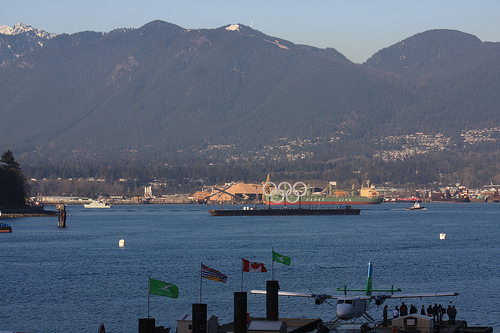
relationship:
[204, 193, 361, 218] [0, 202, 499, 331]
boat in water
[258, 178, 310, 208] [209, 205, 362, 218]
olympic rings on boat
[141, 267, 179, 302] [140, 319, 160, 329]
flag on post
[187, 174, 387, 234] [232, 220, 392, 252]
boat in water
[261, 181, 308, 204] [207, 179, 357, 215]
logo on boat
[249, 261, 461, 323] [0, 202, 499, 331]
airplane on water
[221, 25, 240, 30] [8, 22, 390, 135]
snow on mountain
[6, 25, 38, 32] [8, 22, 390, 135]
snow on mountain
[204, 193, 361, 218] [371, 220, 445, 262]
boat on water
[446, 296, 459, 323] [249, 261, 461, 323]
passengers waiting for airplane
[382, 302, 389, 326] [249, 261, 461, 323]
passengers waiting for airplane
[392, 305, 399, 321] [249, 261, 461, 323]
passengers waiting for airplane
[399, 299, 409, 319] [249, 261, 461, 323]
passengers waiting for airplane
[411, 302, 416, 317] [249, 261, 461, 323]
passengers waiting for airplane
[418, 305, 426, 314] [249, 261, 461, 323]
passengers waiting for airplane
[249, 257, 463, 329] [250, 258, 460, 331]
airplane on pontoons